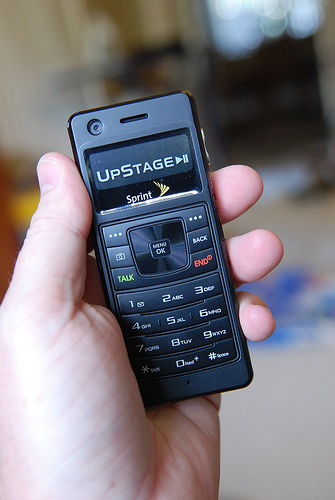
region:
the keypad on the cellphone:
[119, 296, 227, 341]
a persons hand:
[8, 324, 120, 498]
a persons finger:
[212, 174, 264, 196]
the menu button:
[145, 241, 171, 257]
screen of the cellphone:
[88, 152, 195, 190]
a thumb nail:
[35, 167, 59, 187]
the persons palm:
[144, 415, 189, 465]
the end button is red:
[190, 254, 215, 268]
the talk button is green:
[117, 273, 137, 287]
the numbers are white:
[125, 299, 203, 331]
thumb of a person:
[10, 147, 97, 313]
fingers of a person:
[212, 156, 300, 344]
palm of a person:
[7, 309, 239, 490]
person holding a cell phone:
[41, 78, 286, 425]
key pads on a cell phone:
[91, 203, 257, 382]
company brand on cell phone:
[119, 170, 177, 218]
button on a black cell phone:
[190, 245, 219, 268]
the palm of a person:
[2, 305, 238, 499]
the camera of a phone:
[85, 114, 108, 141]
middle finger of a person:
[212, 159, 276, 219]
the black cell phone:
[66, 90, 253, 410]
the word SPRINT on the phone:
[126, 189, 152, 203]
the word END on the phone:
[193, 258, 207, 266]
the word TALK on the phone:
[115, 272, 132, 281]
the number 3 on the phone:
[192, 284, 201, 292]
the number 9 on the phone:
[203, 328, 211, 338]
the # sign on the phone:
[207, 350, 217, 359]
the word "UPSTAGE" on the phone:
[95, 156, 173, 181]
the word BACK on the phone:
[191, 232, 207, 243]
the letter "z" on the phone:
[222, 328, 226, 334]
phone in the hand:
[72, 111, 253, 380]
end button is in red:
[182, 256, 239, 273]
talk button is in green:
[102, 267, 143, 294]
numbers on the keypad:
[121, 282, 232, 371]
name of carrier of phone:
[106, 193, 164, 206]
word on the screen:
[93, 146, 176, 184]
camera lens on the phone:
[94, 112, 104, 140]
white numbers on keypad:
[130, 285, 237, 378]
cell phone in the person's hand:
[72, 101, 274, 443]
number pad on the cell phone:
[124, 291, 224, 358]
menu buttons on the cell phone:
[106, 217, 227, 271]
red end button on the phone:
[188, 252, 221, 272]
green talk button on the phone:
[115, 271, 136, 289]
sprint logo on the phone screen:
[123, 179, 174, 200]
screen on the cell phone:
[83, 135, 201, 198]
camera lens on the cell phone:
[85, 116, 116, 142]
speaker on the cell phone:
[117, 111, 161, 130]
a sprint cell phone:
[55, 88, 261, 447]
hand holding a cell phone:
[12, 91, 304, 495]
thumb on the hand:
[17, 136, 93, 336]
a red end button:
[189, 251, 217, 275]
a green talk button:
[109, 266, 137, 288]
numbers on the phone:
[113, 276, 243, 388]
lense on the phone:
[79, 114, 107, 136]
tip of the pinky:
[235, 288, 278, 348]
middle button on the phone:
[143, 230, 180, 263]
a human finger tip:
[32, 146, 95, 230]